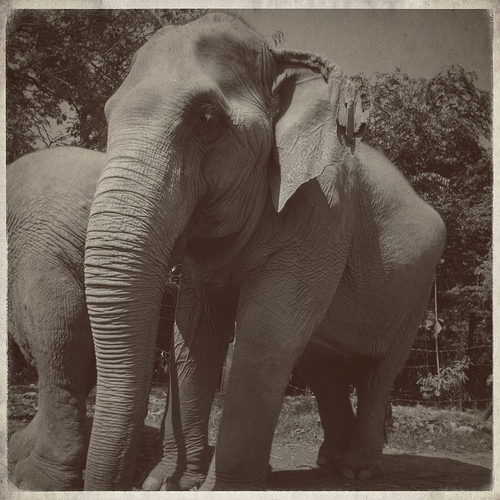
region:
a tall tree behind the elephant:
[341, 57, 487, 412]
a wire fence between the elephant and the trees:
[403, 279, 490, 420]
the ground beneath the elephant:
[255, 438, 493, 498]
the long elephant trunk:
[66, 180, 211, 499]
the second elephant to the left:
[9, 142, 107, 495]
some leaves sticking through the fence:
[418, 367, 470, 400]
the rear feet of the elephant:
[306, 425, 382, 491]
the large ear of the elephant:
[261, 52, 371, 216]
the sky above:
[247, 5, 499, 81]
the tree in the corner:
[10, 5, 146, 151]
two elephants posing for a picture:
[20, 22, 476, 465]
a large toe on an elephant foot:
[145, 472, 165, 488]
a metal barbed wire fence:
[439, 321, 487, 413]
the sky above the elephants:
[327, 12, 467, 67]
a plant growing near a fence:
[417, 360, 479, 417]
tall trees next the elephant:
[24, 10, 99, 127]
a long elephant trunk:
[72, 169, 174, 483]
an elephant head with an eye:
[79, 4, 338, 216]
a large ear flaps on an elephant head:
[279, 47, 358, 207]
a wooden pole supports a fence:
[431, 299, 446, 408]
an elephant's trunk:
[82, 148, 184, 491]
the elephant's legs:
[145, 341, 396, 496]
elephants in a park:
[12, 26, 443, 488]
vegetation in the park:
[430, 298, 487, 414]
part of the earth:
[392, 449, 481, 491]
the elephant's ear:
[272, 50, 369, 217]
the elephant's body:
[309, 189, 448, 347]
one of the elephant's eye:
[193, 105, 225, 125]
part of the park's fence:
[416, 344, 476, 400]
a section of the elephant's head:
[93, 13, 370, 237]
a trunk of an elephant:
[79, 149, 203, 489]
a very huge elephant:
[83, 12, 448, 493]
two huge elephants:
[3, 11, 445, 488]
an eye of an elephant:
[196, 103, 226, 135]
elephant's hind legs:
[307, 363, 394, 478]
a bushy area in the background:
[6, 7, 493, 399]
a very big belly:
[351, 178, 446, 324]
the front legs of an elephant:
[143, 280, 312, 496]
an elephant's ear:
[270, 42, 367, 211]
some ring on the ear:
[341, 80, 358, 148]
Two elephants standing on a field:
[10, 15, 446, 491]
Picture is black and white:
[7, 15, 482, 495]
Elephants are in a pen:
[10, 272, 498, 484]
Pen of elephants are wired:
[413, 305, 493, 414]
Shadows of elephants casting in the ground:
[26, 422, 498, 494]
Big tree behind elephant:
[3, 0, 152, 155]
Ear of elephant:
[262, 40, 375, 215]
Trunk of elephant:
[63, 159, 177, 489]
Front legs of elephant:
[138, 262, 311, 495]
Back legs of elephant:
[307, 341, 401, 486]